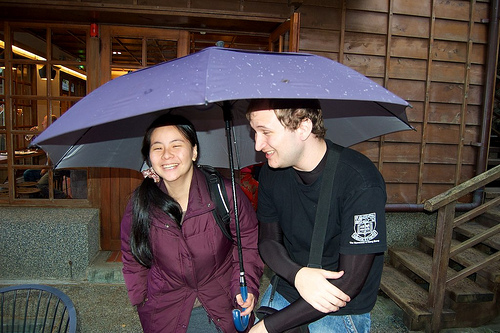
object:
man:
[245, 99, 387, 333]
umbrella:
[31, 47, 417, 172]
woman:
[120, 113, 267, 332]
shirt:
[260, 141, 389, 315]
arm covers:
[257, 221, 374, 333]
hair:
[132, 113, 199, 269]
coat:
[119, 172, 263, 333]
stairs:
[380, 162, 499, 333]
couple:
[119, 99, 385, 333]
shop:
[1, 0, 298, 284]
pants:
[255, 281, 371, 333]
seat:
[0, 286, 81, 333]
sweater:
[258, 142, 388, 333]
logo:
[349, 212, 380, 246]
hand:
[293, 266, 350, 314]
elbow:
[327, 268, 362, 299]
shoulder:
[123, 185, 169, 221]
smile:
[156, 151, 185, 174]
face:
[144, 123, 197, 180]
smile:
[253, 129, 275, 159]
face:
[246, 103, 318, 170]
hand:
[128, 284, 152, 314]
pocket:
[129, 280, 156, 315]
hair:
[268, 97, 330, 140]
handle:
[224, 105, 252, 332]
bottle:
[23, 124, 35, 144]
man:
[27, 114, 70, 200]